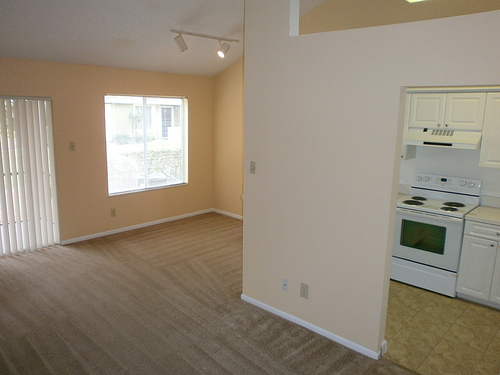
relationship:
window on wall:
[105, 96, 190, 195] [53, 68, 247, 243]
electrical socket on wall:
[299, 281, 310, 300] [246, 28, 400, 354]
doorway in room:
[379, 89, 497, 374] [2, 2, 499, 372]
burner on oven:
[443, 207, 457, 212] [389, 172, 481, 298]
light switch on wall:
[248, 160, 256, 173] [246, 28, 400, 354]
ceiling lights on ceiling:
[174, 30, 237, 59] [3, 2, 242, 72]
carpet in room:
[2, 214, 413, 372] [2, 2, 499, 372]